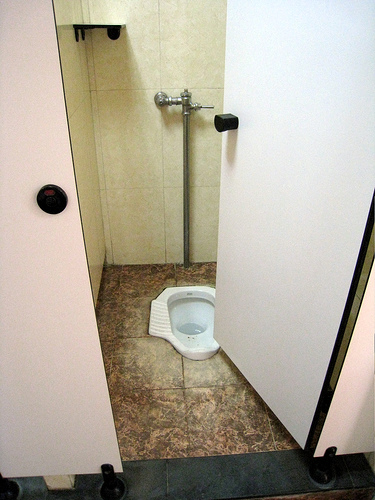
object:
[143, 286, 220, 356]
toilet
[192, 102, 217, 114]
handle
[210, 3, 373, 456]
door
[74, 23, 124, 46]
holder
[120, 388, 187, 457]
tile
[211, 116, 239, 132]
handle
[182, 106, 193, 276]
pipe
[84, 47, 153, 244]
wall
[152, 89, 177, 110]
fixture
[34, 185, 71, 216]
bolt